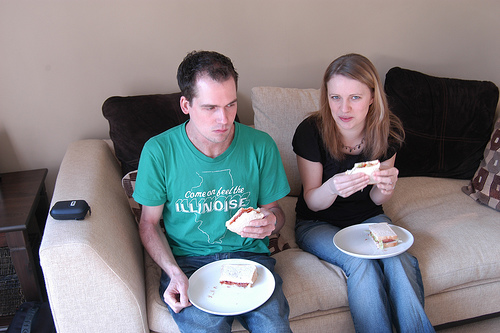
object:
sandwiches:
[225, 205, 265, 237]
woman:
[292, 52, 434, 332]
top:
[292, 117, 400, 227]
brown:
[491, 183, 496, 195]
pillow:
[458, 88, 499, 209]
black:
[58, 204, 71, 212]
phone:
[49, 198, 96, 220]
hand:
[325, 170, 371, 200]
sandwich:
[347, 160, 380, 184]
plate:
[186, 255, 277, 316]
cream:
[70, 145, 122, 201]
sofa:
[38, 65, 499, 332]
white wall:
[0, 0, 500, 200]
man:
[131, 50, 293, 333]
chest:
[171, 164, 253, 202]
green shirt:
[130, 121, 289, 256]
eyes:
[351, 94, 365, 102]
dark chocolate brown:
[112, 106, 159, 132]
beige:
[273, 96, 292, 135]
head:
[325, 54, 373, 133]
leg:
[299, 218, 390, 333]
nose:
[341, 96, 350, 114]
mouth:
[338, 114, 356, 124]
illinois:
[170, 168, 264, 238]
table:
[0, 167, 47, 332]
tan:
[258, 86, 301, 123]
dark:
[414, 89, 470, 148]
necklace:
[329, 141, 376, 154]